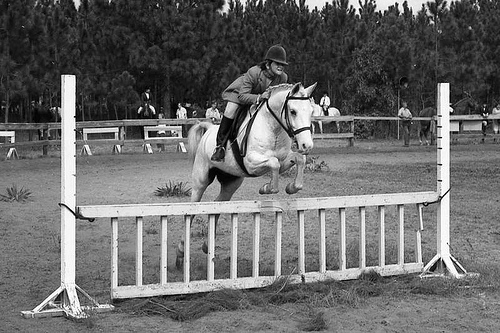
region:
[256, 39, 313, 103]
Person wearing dark helmet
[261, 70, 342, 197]
Black straps on horse's face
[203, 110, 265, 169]
Person wearing black boots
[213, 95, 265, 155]
Light colored pants on person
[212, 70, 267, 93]
Person wearing gray coat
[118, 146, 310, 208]
White horse jumping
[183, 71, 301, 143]
Person riding white horse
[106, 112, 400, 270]
Horse jumping over fence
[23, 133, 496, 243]
Large white wood fence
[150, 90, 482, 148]
People watching in the background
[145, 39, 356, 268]
A horse jumping an obstacle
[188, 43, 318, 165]
A rider on the horse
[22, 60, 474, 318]
A large, white equestrian-jumping obstacle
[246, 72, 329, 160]
The bridle and halter on the horse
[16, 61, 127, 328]
A pole supporting the jumping obstacle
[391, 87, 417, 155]
A person in the distant background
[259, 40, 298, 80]
A hat on the rider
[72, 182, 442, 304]
Rails on the jumping obstacle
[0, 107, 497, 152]
A wooden fence in the distant background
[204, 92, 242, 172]
Boots on the rider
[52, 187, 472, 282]
the frame is wooden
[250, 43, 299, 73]
the hat is black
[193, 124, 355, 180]
the horse is white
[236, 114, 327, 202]
the horse is jumping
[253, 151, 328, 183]
the legs are bent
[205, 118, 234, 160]
the boots are black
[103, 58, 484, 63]
the trees are in the background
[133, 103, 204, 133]
there are people in the background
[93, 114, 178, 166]
the fence is made of wood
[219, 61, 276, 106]
the top is grey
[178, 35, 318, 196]
woman riding a horse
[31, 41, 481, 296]
horse and rider are jumping over a low railing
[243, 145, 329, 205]
horse's front legs are curled inwards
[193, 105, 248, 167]
woman wearing a high dark boot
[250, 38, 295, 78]
hat with the strap fastened under woman's chin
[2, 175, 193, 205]
plants on the ground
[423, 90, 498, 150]
building in the background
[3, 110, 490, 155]
wooden fence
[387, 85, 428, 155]
man leaning on fence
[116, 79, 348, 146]
people riding horses in the background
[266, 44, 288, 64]
The black helmet the rider is wearing.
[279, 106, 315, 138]
The harness around the horse's face.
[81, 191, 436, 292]
The gate the horse is jumping over.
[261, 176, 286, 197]
The left hoof of the horse.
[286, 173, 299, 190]
The right hoof of the horse.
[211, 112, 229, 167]
The black boot on the rider's foot.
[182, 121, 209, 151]
The horse's white tail.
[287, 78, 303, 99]
The horse's left ear.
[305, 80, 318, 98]
The horse's right ear.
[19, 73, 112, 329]
The left post attached to the gate.